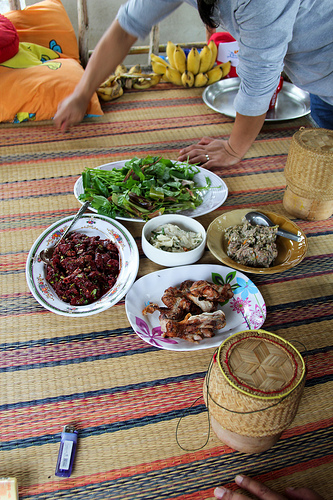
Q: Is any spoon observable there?
A: Yes, there is a spoon.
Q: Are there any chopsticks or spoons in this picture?
A: Yes, there is a spoon.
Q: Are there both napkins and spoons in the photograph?
A: No, there is a spoon but no napkins.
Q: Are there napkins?
A: No, there are no napkins.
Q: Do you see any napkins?
A: No, there are no napkins.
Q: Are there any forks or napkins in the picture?
A: No, there are no napkins or forks.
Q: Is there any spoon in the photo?
A: Yes, there is a spoon.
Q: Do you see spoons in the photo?
A: Yes, there is a spoon.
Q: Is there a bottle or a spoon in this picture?
A: Yes, there is a spoon.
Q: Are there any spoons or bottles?
A: Yes, there is a spoon.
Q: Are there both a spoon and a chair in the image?
A: No, there is a spoon but no chairs.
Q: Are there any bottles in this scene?
A: No, there are no bottles.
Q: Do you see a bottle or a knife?
A: No, there are no bottles or knives.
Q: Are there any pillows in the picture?
A: Yes, there is a pillow.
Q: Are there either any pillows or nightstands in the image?
A: Yes, there is a pillow.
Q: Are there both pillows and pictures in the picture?
A: No, there is a pillow but no pictures.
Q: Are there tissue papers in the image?
A: No, there are no tissue papers.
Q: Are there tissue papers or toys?
A: No, there are no tissue papers or toys.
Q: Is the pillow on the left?
A: Yes, the pillow is on the left of the image.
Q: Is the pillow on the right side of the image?
A: No, the pillow is on the left of the image.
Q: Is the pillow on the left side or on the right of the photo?
A: The pillow is on the left of the image.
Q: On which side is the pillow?
A: The pillow is on the left of the image.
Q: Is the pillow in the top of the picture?
A: Yes, the pillow is in the top of the image.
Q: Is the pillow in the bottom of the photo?
A: No, the pillow is in the top of the image.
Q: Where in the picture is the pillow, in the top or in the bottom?
A: The pillow is in the top of the image.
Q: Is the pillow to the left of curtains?
A: No, the pillow is to the left of the bananas.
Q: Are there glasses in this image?
A: No, there are no glasses.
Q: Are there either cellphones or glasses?
A: No, there are no glasses or cellphones.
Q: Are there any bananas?
A: Yes, there are bananas.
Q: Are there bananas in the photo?
A: Yes, there are bananas.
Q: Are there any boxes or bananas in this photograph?
A: Yes, there are bananas.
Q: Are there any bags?
A: No, there are no bags.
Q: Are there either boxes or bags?
A: No, there are no bags or boxes.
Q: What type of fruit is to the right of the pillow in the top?
A: The fruits are bananas.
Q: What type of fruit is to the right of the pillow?
A: The fruits are bananas.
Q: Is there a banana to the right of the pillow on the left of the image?
A: Yes, there are bananas to the right of the pillow.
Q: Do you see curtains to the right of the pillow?
A: No, there are bananas to the right of the pillow.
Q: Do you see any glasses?
A: No, there are no glasses.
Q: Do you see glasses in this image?
A: No, there are no glasses.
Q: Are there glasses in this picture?
A: No, there are no glasses.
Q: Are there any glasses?
A: No, there are no glasses.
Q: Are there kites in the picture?
A: No, there are no kites.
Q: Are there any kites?
A: No, there are no kites.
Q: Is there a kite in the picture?
A: No, there are no kites.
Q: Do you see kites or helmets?
A: No, there are no kites or helmets.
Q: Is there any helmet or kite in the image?
A: No, there are no kites or helmets.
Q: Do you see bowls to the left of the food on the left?
A: No, the bowl is to the right of the food.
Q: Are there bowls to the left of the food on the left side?
A: No, the bowl is to the right of the food.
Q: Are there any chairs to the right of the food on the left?
A: No, there is a bowl to the right of the food.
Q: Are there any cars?
A: No, there are no cars.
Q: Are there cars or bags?
A: No, there are no cars or bags.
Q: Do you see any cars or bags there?
A: No, there are no cars or bags.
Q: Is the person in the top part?
A: Yes, the person is in the top of the image.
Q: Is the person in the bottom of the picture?
A: No, the person is in the top of the image.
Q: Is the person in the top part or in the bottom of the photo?
A: The person is in the top of the image.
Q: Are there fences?
A: No, there are no fences.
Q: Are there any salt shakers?
A: No, there are no salt shakers.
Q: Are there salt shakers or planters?
A: No, there are no salt shakers or planters.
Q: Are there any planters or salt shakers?
A: No, there are no salt shakers or planters.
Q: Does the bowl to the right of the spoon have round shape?
A: Yes, the bowl is round.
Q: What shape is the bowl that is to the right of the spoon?
A: The bowl is round.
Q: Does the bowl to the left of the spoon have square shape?
A: No, the bowl is round.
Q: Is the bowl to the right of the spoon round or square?
A: The bowl is round.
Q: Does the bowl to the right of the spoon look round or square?
A: The bowl is round.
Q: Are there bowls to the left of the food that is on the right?
A: Yes, there is a bowl to the left of the food.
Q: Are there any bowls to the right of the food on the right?
A: No, the bowl is to the left of the food.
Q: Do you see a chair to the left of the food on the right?
A: No, there is a bowl to the left of the food.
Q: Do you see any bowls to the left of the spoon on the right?
A: Yes, there is a bowl to the left of the spoon.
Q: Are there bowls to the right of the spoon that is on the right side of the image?
A: No, the bowl is to the left of the spoon.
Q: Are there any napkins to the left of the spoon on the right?
A: No, there is a bowl to the left of the spoon.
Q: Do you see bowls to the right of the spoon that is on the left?
A: Yes, there is a bowl to the right of the spoon.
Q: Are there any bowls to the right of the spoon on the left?
A: Yes, there is a bowl to the right of the spoon.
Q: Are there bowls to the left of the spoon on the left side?
A: No, the bowl is to the right of the spoon.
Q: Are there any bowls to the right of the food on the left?
A: Yes, there is a bowl to the right of the food.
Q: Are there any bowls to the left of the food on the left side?
A: No, the bowl is to the right of the food.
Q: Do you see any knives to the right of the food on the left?
A: No, there is a bowl to the right of the food.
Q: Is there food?
A: Yes, there is food.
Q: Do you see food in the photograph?
A: Yes, there is food.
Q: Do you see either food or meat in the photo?
A: Yes, there is food.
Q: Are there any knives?
A: No, there are no knives.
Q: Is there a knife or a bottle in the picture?
A: No, there are no knives or bottles.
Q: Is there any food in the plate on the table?
A: Yes, there is food in the plate.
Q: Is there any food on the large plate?
A: Yes, there is food on the plate.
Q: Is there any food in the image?
A: Yes, there is food.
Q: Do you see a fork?
A: No, there are no forks.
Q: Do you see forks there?
A: No, there are no forks.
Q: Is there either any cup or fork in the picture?
A: No, there are no forks or cups.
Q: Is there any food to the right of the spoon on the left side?
A: Yes, there is food to the right of the spoon.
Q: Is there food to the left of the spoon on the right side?
A: Yes, there is food to the left of the spoon.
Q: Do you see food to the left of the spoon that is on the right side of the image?
A: Yes, there is food to the left of the spoon.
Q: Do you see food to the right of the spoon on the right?
A: No, the food is to the left of the spoon.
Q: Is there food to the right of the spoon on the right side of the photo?
A: No, the food is to the left of the spoon.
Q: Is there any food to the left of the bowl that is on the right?
A: Yes, there is food to the left of the bowl.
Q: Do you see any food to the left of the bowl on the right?
A: Yes, there is food to the left of the bowl.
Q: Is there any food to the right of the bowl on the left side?
A: Yes, there is food to the right of the bowl.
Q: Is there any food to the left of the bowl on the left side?
A: No, the food is to the right of the bowl.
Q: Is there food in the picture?
A: Yes, there is food.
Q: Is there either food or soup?
A: Yes, there is food.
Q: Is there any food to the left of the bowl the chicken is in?
A: Yes, there is food to the left of the bowl.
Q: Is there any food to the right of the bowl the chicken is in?
A: No, the food is to the left of the bowl.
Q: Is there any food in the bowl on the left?
A: Yes, there is food in the bowl.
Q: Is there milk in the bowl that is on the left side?
A: No, there is food in the bowl.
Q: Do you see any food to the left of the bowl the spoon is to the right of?
A: Yes, there is food to the left of the bowl.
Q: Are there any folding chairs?
A: No, there are no folding chairs.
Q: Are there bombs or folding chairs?
A: No, there are no folding chairs or bombs.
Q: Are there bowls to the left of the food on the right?
A: Yes, there is a bowl to the left of the food.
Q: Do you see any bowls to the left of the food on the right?
A: Yes, there is a bowl to the left of the food.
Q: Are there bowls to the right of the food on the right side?
A: No, the bowl is to the left of the food.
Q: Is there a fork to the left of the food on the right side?
A: No, there is a bowl to the left of the food.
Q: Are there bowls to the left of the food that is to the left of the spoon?
A: Yes, there is a bowl to the left of the food.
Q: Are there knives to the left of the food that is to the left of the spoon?
A: No, there is a bowl to the left of the food.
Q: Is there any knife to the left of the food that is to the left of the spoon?
A: No, there is a bowl to the left of the food.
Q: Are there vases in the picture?
A: No, there are no vases.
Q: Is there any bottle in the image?
A: No, there are no bottles.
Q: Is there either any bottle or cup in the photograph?
A: No, there are no bottles or cups.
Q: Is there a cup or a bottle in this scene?
A: No, there are no bottles or cups.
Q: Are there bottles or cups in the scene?
A: No, there are no bottles or cups.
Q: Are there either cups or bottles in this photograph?
A: No, there are no bottles or cups.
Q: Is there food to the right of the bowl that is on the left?
A: Yes, there is food to the right of the bowl.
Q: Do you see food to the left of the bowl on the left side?
A: No, the food is to the right of the bowl.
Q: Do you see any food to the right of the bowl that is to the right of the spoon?
A: Yes, there is food to the right of the bowl.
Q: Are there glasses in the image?
A: No, there are no glasses.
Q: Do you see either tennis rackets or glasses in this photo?
A: No, there are no glasses or tennis rackets.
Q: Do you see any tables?
A: Yes, there is a table.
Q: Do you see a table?
A: Yes, there is a table.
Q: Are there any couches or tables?
A: Yes, there is a table.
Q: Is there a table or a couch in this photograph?
A: Yes, there is a table.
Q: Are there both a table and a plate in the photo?
A: Yes, there are both a table and a plate.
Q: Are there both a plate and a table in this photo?
A: Yes, there are both a table and a plate.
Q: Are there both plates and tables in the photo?
A: Yes, there are both a table and a plate.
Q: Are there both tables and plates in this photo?
A: Yes, there are both a table and a plate.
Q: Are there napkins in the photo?
A: No, there are no napkins.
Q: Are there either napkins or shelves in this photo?
A: No, there are no napkins or shelves.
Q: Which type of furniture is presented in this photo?
A: The furniture is a table.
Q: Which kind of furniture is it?
A: The piece of furniture is a table.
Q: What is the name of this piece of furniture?
A: That is a table.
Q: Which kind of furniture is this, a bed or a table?
A: That is a table.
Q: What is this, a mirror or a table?
A: This is a table.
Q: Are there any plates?
A: Yes, there is a plate.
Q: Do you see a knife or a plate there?
A: Yes, there is a plate.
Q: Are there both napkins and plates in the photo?
A: No, there is a plate but no napkins.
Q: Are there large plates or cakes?
A: Yes, there is a large plate.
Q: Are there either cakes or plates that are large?
A: Yes, the plate is large.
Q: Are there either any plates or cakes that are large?
A: Yes, the plate is large.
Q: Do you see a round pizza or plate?
A: Yes, there is a round plate.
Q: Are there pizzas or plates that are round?
A: Yes, the plate is round.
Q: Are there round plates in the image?
A: Yes, there is a round plate.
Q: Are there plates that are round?
A: Yes, there is a plate that is round.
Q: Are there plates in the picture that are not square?
A: Yes, there is a round plate.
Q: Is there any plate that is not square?
A: Yes, there is a round plate.